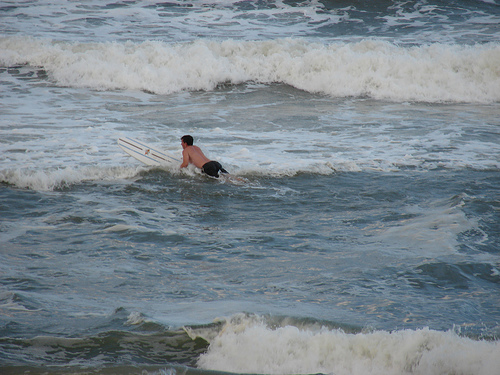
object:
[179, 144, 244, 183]
body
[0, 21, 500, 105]
wave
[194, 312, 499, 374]
bubbles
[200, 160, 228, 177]
shorts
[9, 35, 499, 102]
foam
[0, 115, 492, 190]
foam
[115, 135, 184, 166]
surfboard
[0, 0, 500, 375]
water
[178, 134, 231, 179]
surfer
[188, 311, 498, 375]
wave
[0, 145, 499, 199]
wave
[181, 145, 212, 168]
bare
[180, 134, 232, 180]
man/water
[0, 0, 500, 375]
ocean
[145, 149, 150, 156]
logo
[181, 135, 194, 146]
hair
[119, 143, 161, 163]
stripe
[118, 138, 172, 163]
stripe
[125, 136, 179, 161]
stripe